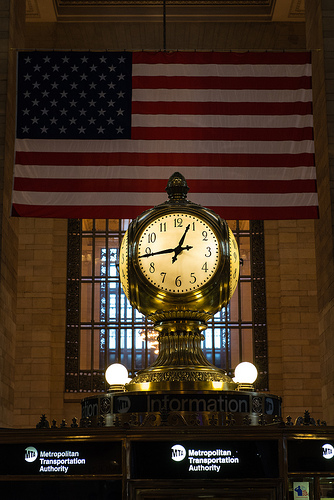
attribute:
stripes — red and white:
[231, 143, 269, 188]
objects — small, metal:
[36, 410, 89, 428]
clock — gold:
[86, 178, 262, 391]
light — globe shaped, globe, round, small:
[97, 355, 133, 387]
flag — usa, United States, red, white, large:
[8, 41, 332, 228]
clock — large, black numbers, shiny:
[104, 166, 251, 333]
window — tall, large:
[60, 212, 278, 381]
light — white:
[225, 356, 262, 389]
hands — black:
[136, 221, 195, 265]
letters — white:
[74, 393, 296, 432]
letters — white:
[17, 442, 90, 482]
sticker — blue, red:
[313, 437, 332, 467]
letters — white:
[35, 462, 68, 474]